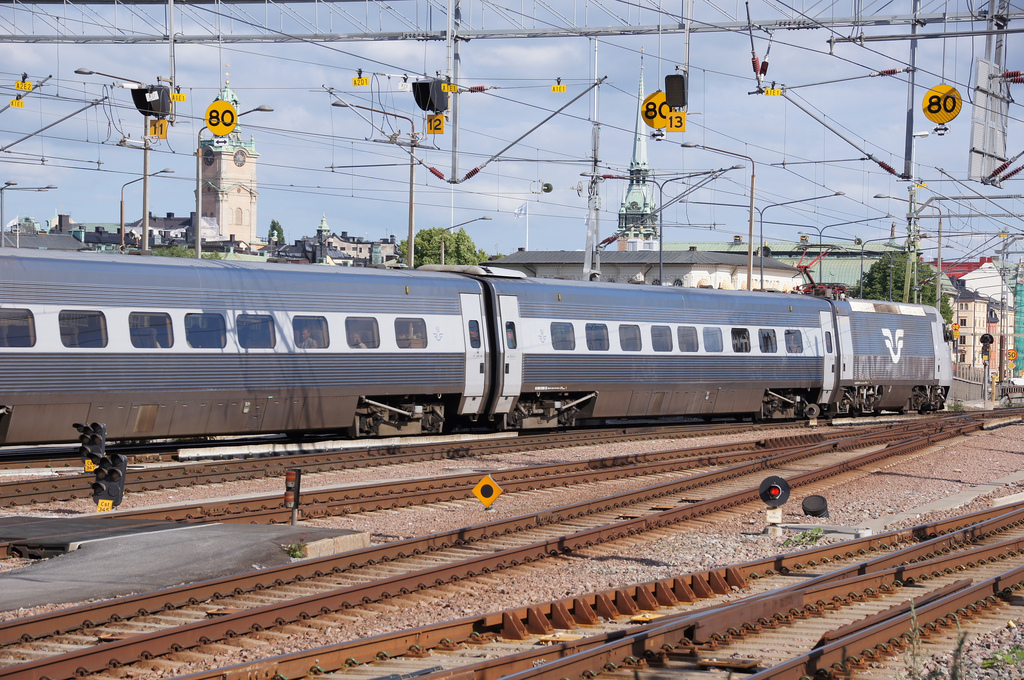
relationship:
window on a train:
[0, 308, 38, 348] [2, 240, 964, 441]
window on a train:
[58, 310, 107, 348] [2, 240, 964, 441]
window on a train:
[129, 311, 175, 347] [2, 240, 964, 441]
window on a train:
[184, 313, 227, 348] [2, 240, 964, 441]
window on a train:
[236, 314, 275, 349] [2, 240, 964, 441]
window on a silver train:
[0, 308, 38, 348] [2, 240, 964, 441]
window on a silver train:
[58, 310, 107, 348] [2, 240, 964, 441]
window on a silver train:
[129, 311, 175, 347] [2, 240, 964, 441]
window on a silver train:
[184, 313, 227, 348] [2, 240, 964, 441]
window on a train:
[0, 308, 38, 348] [2, 212, 962, 409]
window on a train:
[58, 310, 107, 348] [2, 212, 962, 409]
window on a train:
[125, 305, 175, 347] [2, 212, 962, 409]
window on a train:
[177, 307, 230, 349] [2, 212, 962, 409]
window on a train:
[237, 307, 281, 351] [2, 212, 962, 409]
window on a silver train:
[237, 307, 281, 351] [2, 240, 964, 441]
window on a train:
[52, 297, 111, 345] [2, 240, 964, 441]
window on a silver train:
[4, 305, 35, 349] [2, 240, 964, 441]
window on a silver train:
[236, 314, 275, 349] [2, 240, 964, 441]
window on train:
[184, 313, 227, 348] [8, 246, 955, 461]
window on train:
[236, 314, 275, 349] [8, 246, 955, 461]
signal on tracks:
[79, 431, 114, 516] [12, 403, 1013, 678]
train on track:
[2, 240, 964, 441] [2, 397, 1012, 668]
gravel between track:
[21, 451, 747, 518] [0, 406, 1024, 680]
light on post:
[760, 472, 791, 511] [762, 503, 784, 536]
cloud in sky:
[341, 30, 558, 93] [4, 3, 1016, 306]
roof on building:
[944, 258, 986, 272] [922, 254, 1009, 391]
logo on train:
[883, 327, 909, 371] [2, 240, 964, 441]